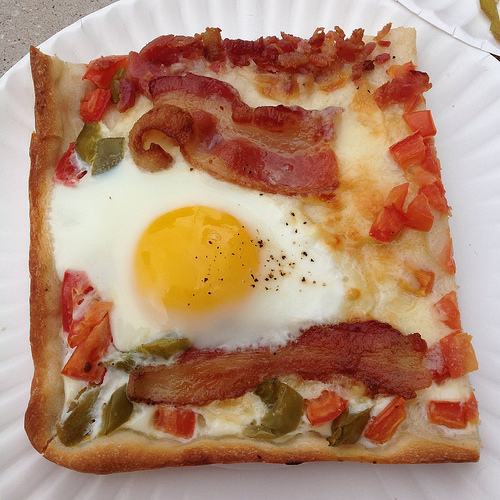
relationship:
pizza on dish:
[28, 53, 483, 463] [6, 5, 489, 492]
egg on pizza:
[57, 159, 331, 344] [28, 53, 483, 463]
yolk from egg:
[134, 203, 261, 317] [57, 159, 331, 344]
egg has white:
[57, 159, 331, 344] [65, 189, 134, 246]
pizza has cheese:
[28, 53, 483, 463] [342, 101, 389, 199]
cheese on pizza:
[342, 101, 389, 199] [28, 53, 483, 463]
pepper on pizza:
[65, 382, 135, 441] [28, 53, 483, 463]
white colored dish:
[431, 53, 500, 135] [6, 5, 489, 492]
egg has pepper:
[57, 159, 331, 344] [200, 229, 318, 297]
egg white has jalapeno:
[65, 189, 134, 246] [80, 125, 125, 169]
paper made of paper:
[6, 5, 489, 492] [431, 53, 500, 135]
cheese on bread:
[342, 101, 389, 199] [28, 53, 483, 463]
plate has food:
[6, 5, 489, 492] [28, 53, 483, 463]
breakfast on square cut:
[63, 75, 418, 388] [28, 53, 483, 463]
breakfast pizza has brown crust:
[28, 53, 483, 463] [22, 45, 80, 479]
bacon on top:
[136, 69, 336, 200] [63, 75, 418, 388]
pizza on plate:
[28, 53, 483, 463] [6, 5, 489, 492]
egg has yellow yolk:
[57, 159, 331, 344] [134, 203, 261, 317]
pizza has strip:
[28, 53, 483, 463] [136, 69, 336, 200]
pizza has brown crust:
[28, 53, 483, 463] [22, 45, 80, 479]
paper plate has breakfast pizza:
[6, 5, 489, 492] [28, 53, 483, 463]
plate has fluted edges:
[6, 5, 489, 492] [74, 1, 432, 30]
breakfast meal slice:
[63, 75, 418, 388] [21, 302, 160, 472]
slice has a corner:
[21, 302, 160, 472] [23, 378, 126, 477]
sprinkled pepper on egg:
[200, 229, 318, 297] [57, 159, 331, 344]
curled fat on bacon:
[132, 71, 193, 171] [136, 69, 336, 200]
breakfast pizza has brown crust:
[28, 53, 483, 463] [22, 45, 133, 479]